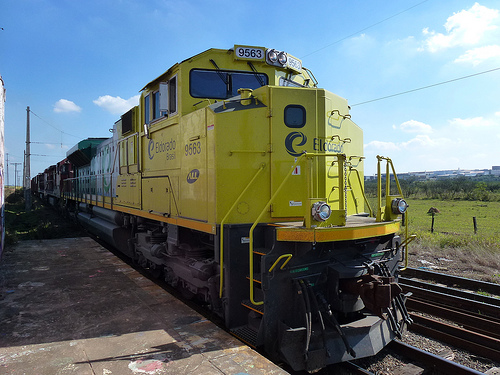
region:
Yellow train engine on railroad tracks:
[80, 39, 402, 365]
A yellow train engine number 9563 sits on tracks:
[80, 45, 403, 358]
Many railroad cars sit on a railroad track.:
[26, 18, 432, 364]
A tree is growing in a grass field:
[418, 197, 447, 247]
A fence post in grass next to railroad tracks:
[440, 215, 497, 366]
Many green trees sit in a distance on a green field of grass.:
[413, 170, 498, 206]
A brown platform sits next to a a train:
[1, 237, 247, 369]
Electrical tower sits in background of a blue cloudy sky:
[3, 89, 53, 217]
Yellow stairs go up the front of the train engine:
[214, 155, 422, 307]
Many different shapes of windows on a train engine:
[137, 35, 337, 130]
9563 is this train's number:
[234, 43, 265, 60]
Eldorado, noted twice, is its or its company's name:
[150, 131, 343, 154]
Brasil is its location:
[161, 148, 178, 164]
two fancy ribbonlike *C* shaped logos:
[142, 127, 314, 167]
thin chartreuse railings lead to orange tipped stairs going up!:
[208, 143, 346, 311]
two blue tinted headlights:
[311, 196, 411, 223]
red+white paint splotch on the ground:
[121, 344, 177, 374]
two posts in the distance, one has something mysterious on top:
[423, 203, 480, 235]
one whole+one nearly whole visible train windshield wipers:
[208, 56, 313, 102]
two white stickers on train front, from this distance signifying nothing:
[285, 163, 304, 211]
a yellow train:
[56, 58, 462, 352]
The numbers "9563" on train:
[158, 126, 278, 178]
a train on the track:
[105, 64, 486, 365]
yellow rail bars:
[197, 132, 402, 344]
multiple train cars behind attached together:
[25, 116, 302, 295]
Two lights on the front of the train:
[273, 182, 434, 255]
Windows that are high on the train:
[107, 69, 321, 126]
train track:
[428, 279, 493, 369]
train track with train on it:
[208, 169, 493, 368]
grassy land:
[381, 172, 496, 303]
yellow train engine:
[94, 37, 426, 374]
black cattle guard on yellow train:
[268, 224, 418, 374]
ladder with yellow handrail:
[213, 150, 410, 351]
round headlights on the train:
[310, 185, 410, 232]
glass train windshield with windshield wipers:
[181, 62, 272, 104]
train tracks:
[407, 255, 499, 371]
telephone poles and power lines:
[6, 82, 61, 238]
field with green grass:
[414, 179, 499, 236]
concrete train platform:
[7, 267, 129, 368]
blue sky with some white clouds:
[32, 59, 104, 126]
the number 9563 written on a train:
[232, 42, 268, 63]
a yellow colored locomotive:
[8, 35, 467, 372]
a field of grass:
[409, 193, 499, 248]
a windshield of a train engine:
[189, 61, 271, 101]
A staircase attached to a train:
[219, 209, 301, 340]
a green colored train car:
[62, 131, 119, 235]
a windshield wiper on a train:
[206, 56, 236, 87]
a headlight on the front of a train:
[309, 196, 337, 226]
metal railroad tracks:
[416, 256, 498, 373]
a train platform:
[16, 236, 293, 373]